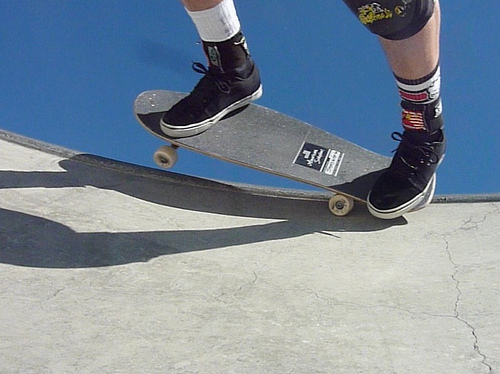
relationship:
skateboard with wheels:
[134, 86, 436, 215] [150, 149, 354, 219]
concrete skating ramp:
[0, 127, 496, 372] [6, 120, 498, 371]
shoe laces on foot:
[184, 59, 242, 96] [150, 57, 267, 139]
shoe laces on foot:
[380, 118, 439, 172] [352, 131, 437, 214]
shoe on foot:
[356, 117, 451, 224] [365, 117, 447, 223]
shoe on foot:
[156, 57, 262, 140] [156, 55, 266, 142]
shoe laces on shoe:
[184, 59, 241, 95] [154, 50, 261, 132]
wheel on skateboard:
[326, 193, 355, 217] [134, 86, 436, 215]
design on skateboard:
[296, 141, 347, 176] [86, 51, 457, 238]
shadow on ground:
[52, 142, 277, 359] [4, 85, 491, 334]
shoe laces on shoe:
[389, 130, 441, 166] [366, 117, 452, 219]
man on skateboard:
[155, 2, 449, 226] [130, 83, 446, 222]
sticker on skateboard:
[292, 140, 349, 179] [130, 83, 446, 222]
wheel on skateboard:
[322, 190, 356, 225] [132, 72, 445, 231]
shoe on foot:
[138, 42, 305, 149] [151, 32, 451, 218]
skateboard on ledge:
[134, 86, 436, 215] [1, 116, 499, 202]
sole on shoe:
[159, 82, 268, 137] [158, 32, 267, 140]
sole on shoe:
[359, 169, 438, 220] [366, 100, 446, 222]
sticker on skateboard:
[292, 138, 354, 183] [130, 83, 446, 222]